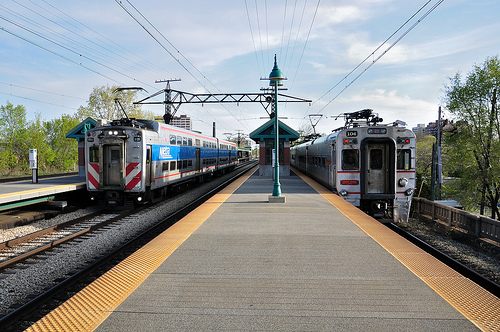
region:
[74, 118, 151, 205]
end of train with red and white stripes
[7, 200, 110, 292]
train tracks and rails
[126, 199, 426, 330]
wooden train platform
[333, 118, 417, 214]
train with red lights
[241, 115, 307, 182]
small hut on train platform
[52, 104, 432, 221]
train platform between two trains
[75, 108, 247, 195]
train with blue stripe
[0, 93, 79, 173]
green leaves on trees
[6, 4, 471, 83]
power lines and sky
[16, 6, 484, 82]
wispy white clouds in sky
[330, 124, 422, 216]
the back of a train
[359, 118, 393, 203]
the back door of a train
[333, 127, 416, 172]
windows of a train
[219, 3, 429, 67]
bunch of power lines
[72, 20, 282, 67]
a sky full of clouds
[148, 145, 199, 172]
windows on a train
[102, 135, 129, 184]
door of a train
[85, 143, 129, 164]
windows of a train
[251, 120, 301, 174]
a train station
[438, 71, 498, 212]
trees and bushes on side of a track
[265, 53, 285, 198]
a green light post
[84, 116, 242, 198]
a train on the tracks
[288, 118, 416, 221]
a train on the tracks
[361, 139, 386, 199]
door on a train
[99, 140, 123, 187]
door on a train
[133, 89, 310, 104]
a black metal rail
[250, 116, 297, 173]
a small covering for train station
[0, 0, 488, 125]
wires for trains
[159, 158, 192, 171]
windows on a train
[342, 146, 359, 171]
window on a train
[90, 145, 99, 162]
glass window on train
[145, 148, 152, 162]
glass window on train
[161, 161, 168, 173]
glass window on train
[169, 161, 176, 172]
glass window on train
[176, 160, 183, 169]
glass window on train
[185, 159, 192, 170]
glass window on train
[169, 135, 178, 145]
glass window on train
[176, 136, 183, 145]
glass window on train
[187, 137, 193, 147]
glass window on train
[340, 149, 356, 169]
glass window on train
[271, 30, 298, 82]
part of a wiore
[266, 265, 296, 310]
part fo a flooor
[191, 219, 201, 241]
aprt of a line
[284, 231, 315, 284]
part of a floor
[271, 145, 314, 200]
part of a stand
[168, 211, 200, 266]
aprt of a line